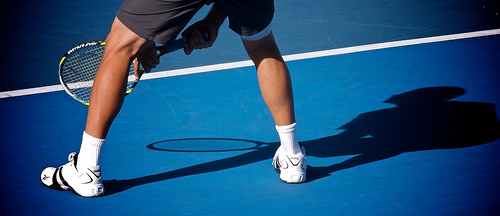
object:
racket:
[57, 30, 219, 106]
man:
[37, 2, 317, 199]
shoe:
[41, 151, 112, 199]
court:
[0, 0, 499, 216]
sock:
[74, 130, 106, 168]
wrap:
[240, 21, 277, 42]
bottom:
[155, 32, 212, 57]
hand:
[179, 20, 220, 55]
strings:
[59, 43, 136, 102]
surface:
[149, 90, 213, 122]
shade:
[100, 87, 499, 196]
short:
[118, 0, 278, 45]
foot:
[269, 141, 311, 184]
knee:
[101, 30, 143, 59]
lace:
[58, 152, 80, 168]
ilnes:
[0, 29, 500, 102]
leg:
[70, 0, 210, 168]